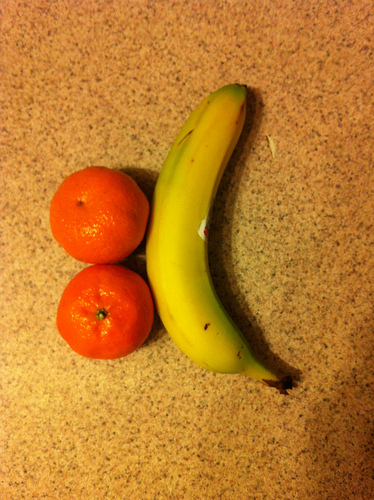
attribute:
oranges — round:
[47, 164, 156, 360]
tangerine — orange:
[53, 268, 148, 360]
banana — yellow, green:
[147, 78, 304, 395]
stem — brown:
[246, 357, 295, 394]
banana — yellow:
[156, 82, 292, 397]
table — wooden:
[55, 64, 153, 143]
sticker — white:
[196, 215, 211, 239]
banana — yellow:
[131, 68, 316, 398]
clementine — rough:
[51, 266, 150, 364]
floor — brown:
[0, 0, 372, 498]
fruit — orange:
[29, 156, 154, 383]